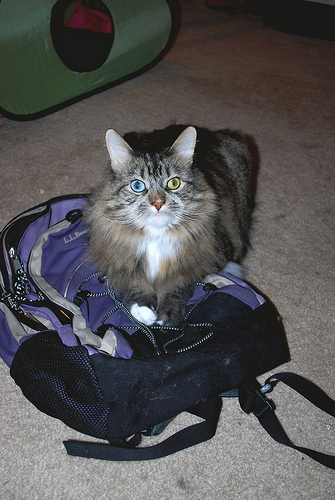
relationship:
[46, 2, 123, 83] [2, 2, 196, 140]
opening to tent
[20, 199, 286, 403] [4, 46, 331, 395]
backpack lying on carpet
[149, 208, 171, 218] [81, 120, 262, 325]
mouth of a cat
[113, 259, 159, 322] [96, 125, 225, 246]
leg of a cat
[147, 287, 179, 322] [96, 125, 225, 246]
leg of a cat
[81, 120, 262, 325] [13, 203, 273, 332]
cat lying on backpack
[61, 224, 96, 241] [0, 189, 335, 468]
l.l. bean written on backpack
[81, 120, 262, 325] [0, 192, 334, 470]
cat sitting on backpack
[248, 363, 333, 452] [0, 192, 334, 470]
straps on backpack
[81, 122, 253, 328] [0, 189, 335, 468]
cat lying on backpack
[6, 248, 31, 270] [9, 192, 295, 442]
zipper on backpack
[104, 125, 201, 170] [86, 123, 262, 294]
ears on cat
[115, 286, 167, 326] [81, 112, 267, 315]
paw on cat